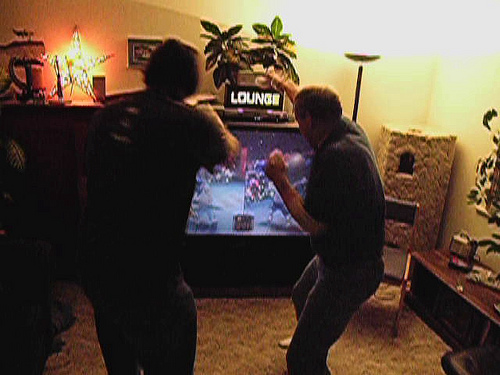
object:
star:
[41, 21, 115, 103]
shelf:
[4, 92, 121, 120]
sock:
[278, 335, 294, 347]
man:
[265, 70, 386, 375]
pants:
[91, 271, 199, 374]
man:
[76, 38, 243, 373]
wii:
[55, 102, 108, 160]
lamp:
[344, 53, 380, 128]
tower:
[373, 118, 457, 252]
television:
[181, 123, 317, 237]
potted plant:
[198, 15, 300, 113]